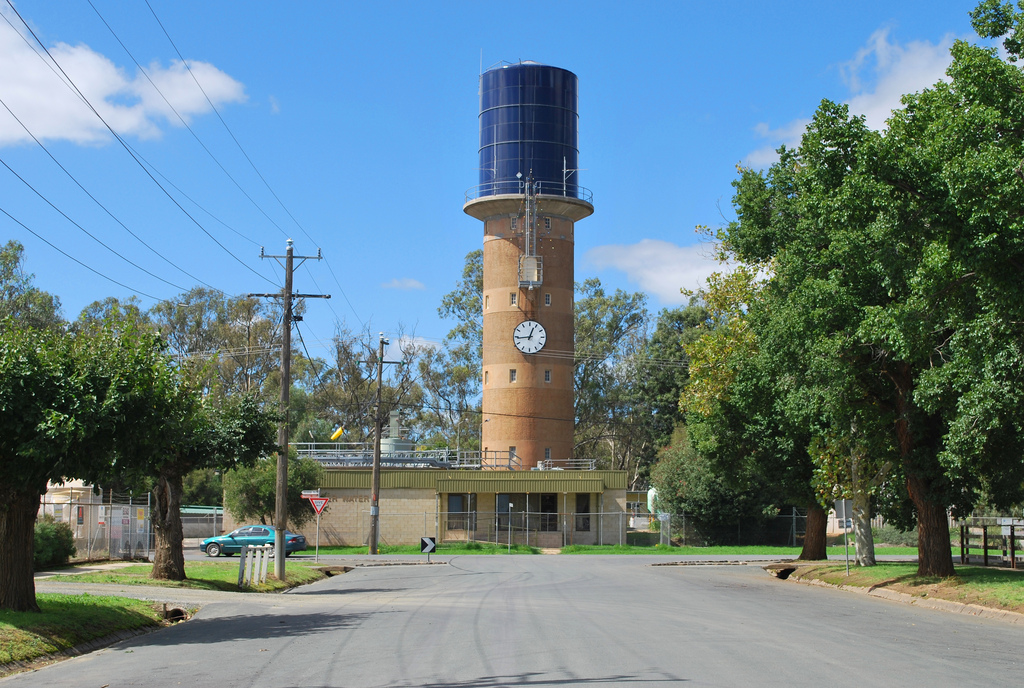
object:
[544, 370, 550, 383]
glass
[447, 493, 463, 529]
glass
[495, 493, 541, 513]
glass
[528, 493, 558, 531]
glass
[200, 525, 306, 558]
car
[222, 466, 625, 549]
building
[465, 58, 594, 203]
tower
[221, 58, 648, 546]
building